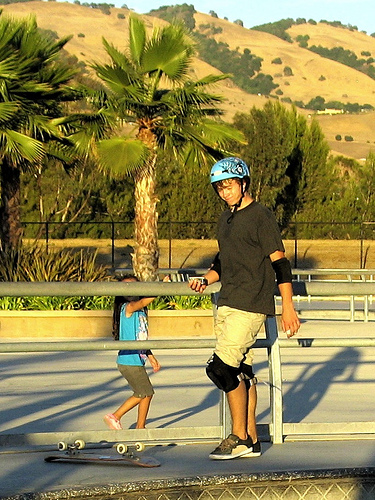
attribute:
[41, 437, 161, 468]
skateboard — overturned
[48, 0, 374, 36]
sky — in the picture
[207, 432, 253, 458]
sneaker — yellow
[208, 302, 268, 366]
shorts — khaki 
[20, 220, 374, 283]
railing — black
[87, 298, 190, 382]
shirt — blue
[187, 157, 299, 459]
man — light skinned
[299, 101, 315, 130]
ground — in the picture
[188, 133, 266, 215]
helmet — blue 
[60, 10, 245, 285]
palm tree — green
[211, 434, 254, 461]
sneaker — yellow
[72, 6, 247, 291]
palm tree — in the picture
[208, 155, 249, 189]
helmet — blue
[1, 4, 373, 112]
hills — in the picture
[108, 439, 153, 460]
wheels — yellow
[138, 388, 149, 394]
button — brown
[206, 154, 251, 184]
helmet — in the picture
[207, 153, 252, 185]
helmet — light , blue 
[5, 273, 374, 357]
railing — thick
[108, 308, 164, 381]
tshirt — blue 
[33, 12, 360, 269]
hills — dry 